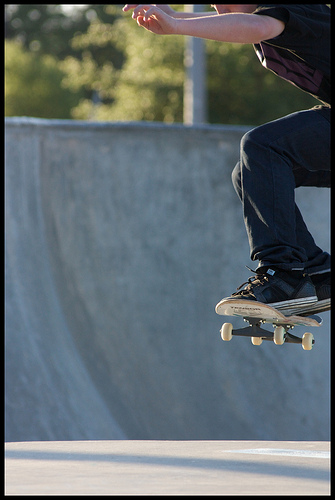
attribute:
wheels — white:
[215, 319, 315, 358]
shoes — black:
[225, 255, 334, 319]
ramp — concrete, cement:
[4, 113, 329, 440]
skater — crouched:
[101, 6, 333, 352]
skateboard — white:
[157, 254, 309, 407]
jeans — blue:
[223, 104, 331, 266]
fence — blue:
[14, 68, 241, 313]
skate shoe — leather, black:
[240, 267, 301, 316]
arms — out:
[122, 2, 285, 43]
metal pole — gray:
[179, 4, 213, 124]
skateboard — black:
[212, 297, 334, 349]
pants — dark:
[218, 117, 330, 264]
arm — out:
[119, 2, 285, 43]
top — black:
[243, 3, 330, 104]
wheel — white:
[273, 325, 285, 344]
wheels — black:
[250, 335, 315, 348]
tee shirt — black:
[251, 2, 334, 109]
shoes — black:
[247, 279, 332, 311]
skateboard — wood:
[216, 296, 333, 352]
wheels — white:
[214, 323, 318, 349]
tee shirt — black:
[255, 7, 329, 105]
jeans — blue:
[224, 94, 325, 294]